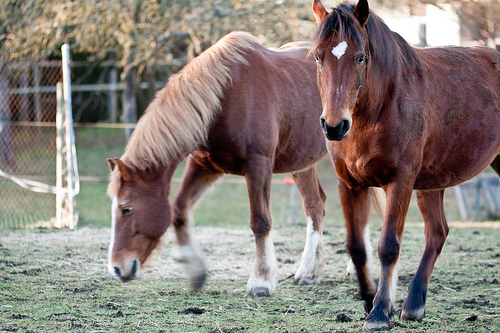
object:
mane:
[104, 30, 255, 201]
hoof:
[363, 312, 391, 331]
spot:
[331, 41, 348, 60]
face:
[311, 20, 365, 124]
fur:
[322, 44, 500, 190]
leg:
[291, 164, 327, 267]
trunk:
[119, 69, 138, 139]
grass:
[0, 225, 500, 333]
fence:
[0, 42, 81, 227]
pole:
[53, 81, 65, 229]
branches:
[0, 0, 315, 105]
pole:
[292, 182, 298, 225]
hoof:
[363, 302, 396, 321]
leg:
[170, 158, 224, 265]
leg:
[337, 186, 378, 290]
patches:
[377, 229, 400, 267]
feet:
[245, 284, 275, 298]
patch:
[331, 41, 348, 60]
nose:
[308, 0, 420, 84]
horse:
[104, 29, 389, 296]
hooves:
[248, 287, 271, 299]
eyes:
[358, 55, 364, 63]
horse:
[304, 0, 500, 333]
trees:
[0, 0, 310, 112]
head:
[106, 157, 170, 283]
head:
[304, 0, 373, 141]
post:
[61, 43, 77, 230]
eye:
[122, 206, 134, 215]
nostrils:
[341, 120, 349, 133]